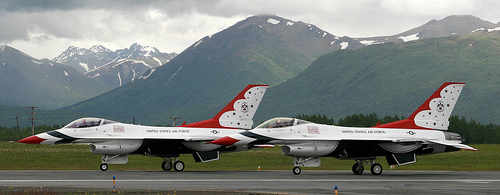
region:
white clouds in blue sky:
[37, 30, 170, 83]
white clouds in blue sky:
[259, 35, 285, 50]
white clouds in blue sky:
[405, 9, 455, 64]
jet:
[29, 90, 271, 159]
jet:
[277, 81, 488, 171]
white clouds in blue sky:
[74, 14, 126, 50]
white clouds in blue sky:
[310, 11, 346, 34]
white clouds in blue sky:
[137, 0, 181, 31]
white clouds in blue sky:
[58, 68, 115, 101]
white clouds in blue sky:
[126, 14, 162, 53]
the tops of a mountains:
[5, 36, 165, 82]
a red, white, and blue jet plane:
[14, 83, 270, 174]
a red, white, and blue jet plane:
[201, 79, 484, 178]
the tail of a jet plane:
[193, 76, 261, 130]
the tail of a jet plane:
[372, 79, 466, 129]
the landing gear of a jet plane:
[367, 160, 383, 177]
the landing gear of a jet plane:
[96, 154, 111, 173]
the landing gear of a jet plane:
[350, 156, 362, 173]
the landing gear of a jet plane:
[288, 160, 303, 176]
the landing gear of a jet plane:
[171, 153, 188, 173]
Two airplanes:
[18, 74, 488, 175]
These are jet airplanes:
[11, 73, 487, 175]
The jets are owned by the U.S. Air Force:
[15, 56, 484, 178]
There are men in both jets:
[13, 91, 324, 161]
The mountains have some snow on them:
[52, 8, 337, 77]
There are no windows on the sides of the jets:
[115, 128, 395, 159]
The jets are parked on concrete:
[88, 148, 409, 178]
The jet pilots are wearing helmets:
[13, 97, 328, 155]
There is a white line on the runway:
[26, 169, 440, 189]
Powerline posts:
[8, 91, 45, 135]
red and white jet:
[34, 72, 267, 164]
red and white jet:
[232, 70, 497, 179]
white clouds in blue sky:
[36, 18, 77, 52]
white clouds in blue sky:
[97, 5, 143, 43]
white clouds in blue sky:
[178, 23, 228, 48]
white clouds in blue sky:
[261, 10, 286, 32]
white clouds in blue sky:
[337, 13, 408, 51]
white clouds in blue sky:
[399, 2, 452, 41]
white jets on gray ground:
[5, 60, 490, 185]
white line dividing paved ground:
[0, 170, 485, 190]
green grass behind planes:
[0, 140, 490, 165]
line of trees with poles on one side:
[0, 110, 490, 140]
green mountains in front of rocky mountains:
[5, 15, 495, 120]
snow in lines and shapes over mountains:
[2, 11, 497, 81]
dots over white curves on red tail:
[181, 80, 261, 125]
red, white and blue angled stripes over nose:
[16, 131, 76, 143]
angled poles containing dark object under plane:
[187, 146, 222, 161]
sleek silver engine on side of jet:
[85, 141, 140, 151]